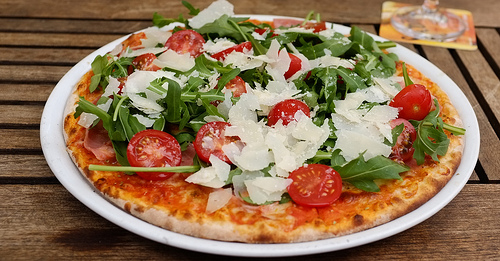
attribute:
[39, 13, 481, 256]
plate — white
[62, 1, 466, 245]
pizza — small, whole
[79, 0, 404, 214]
sliced cheese — fresh, thin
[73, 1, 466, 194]
dandelions — green, uncooked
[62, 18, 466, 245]
crust — golden, thin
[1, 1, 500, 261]
table — wooden, dark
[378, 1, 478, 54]
coaster — orange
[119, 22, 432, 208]
tomato slices — uncooked, red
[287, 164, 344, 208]
tomato — red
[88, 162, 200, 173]
stem — green, thin